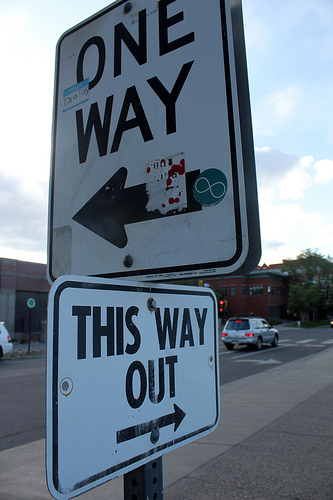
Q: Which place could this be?
A: It is a street.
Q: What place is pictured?
A: It is a street.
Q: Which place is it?
A: It is a street.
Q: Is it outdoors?
A: Yes, it is outdoors.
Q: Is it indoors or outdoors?
A: It is outdoors.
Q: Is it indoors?
A: No, it is outdoors.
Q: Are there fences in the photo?
A: No, there are no fences.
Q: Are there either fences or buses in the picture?
A: No, there are no fences or buses.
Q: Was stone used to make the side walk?
A: Yes, the side walk is made of stone.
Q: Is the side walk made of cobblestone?
A: No, the side walk is made of stone.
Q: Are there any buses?
A: No, there are no buses.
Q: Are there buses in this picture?
A: No, there are no buses.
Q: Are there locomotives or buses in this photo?
A: No, there are no buses or locomotives.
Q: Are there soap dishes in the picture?
A: No, there are no soap dishes.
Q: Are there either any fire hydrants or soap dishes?
A: No, there are no soap dishes or fire hydrants.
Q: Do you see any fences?
A: No, there are no fences.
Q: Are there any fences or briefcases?
A: No, there are no fences or briefcases.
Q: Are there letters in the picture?
A: Yes, there are letters.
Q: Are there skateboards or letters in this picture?
A: Yes, there are letters.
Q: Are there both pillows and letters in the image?
A: No, there are letters but no pillows.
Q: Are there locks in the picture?
A: No, there are no locks.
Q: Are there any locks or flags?
A: No, there are no locks or flags.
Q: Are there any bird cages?
A: No, there are no bird cages.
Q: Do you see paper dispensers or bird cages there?
A: No, there are no bird cages or paper dispensers.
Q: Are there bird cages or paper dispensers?
A: No, there are no bird cages or paper dispensers.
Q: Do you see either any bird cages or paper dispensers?
A: No, there are no bird cages or paper dispensers.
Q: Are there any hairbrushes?
A: No, there are no hairbrushes.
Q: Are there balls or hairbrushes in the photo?
A: No, there are no hairbrushes or balls.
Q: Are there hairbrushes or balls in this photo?
A: No, there are no hairbrushes or balls.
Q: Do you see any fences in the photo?
A: No, there are no fences.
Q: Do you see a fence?
A: No, there are no fences.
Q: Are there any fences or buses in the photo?
A: No, there are no buses or fences.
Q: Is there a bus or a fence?
A: No, there are no buses or fences.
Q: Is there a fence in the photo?
A: No, there are no fences.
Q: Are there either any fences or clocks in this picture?
A: No, there are no fences or clocks.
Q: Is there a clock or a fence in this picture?
A: No, there are no fences or clocks.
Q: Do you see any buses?
A: No, there are no buses.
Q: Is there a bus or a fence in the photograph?
A: No, there are no buses or fences.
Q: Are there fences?
A: No, there are no fences.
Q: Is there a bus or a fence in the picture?
A: No, there are no fences or buses.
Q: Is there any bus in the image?
A: No, there are no buses.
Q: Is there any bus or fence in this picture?
A: No, there are no buses or fences.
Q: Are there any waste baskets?
A: No, there are no waste baskets.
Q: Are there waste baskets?
A: No, there are no waste baskets.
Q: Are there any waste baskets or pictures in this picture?
A: No, there are no waste baskets or pictures.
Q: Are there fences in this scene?
A: No, there are no fences.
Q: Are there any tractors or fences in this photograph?
A: No, there are no fences or tractors.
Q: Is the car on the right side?
A: Yes, the car is on the right of the image.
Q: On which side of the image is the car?
A: The car is on the right of the image.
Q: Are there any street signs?
A: Yes, there is a street sign.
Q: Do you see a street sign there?
A: Yes, there is a street sign.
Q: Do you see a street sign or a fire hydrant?
A: Yes, there is a street sign.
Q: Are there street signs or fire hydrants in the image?
A: Yes, there is a street sign.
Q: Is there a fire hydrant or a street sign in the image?
A: Yes, there is a street sign.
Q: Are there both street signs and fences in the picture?
A: No, there is a street sign but no fences.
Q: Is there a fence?
A: No, there are no fences.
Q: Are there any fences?
A: No, there are no fences.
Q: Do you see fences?
A: No, there are no fences.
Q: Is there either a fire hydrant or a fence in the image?
A: No, there are no fences or fire hydrants.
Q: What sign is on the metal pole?
A: The sign is a street sign.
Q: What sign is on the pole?
A: The sign is a street sign.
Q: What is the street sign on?
A: The street sign is on the pole.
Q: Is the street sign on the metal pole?
A: Yes, the street sign is on the pole.